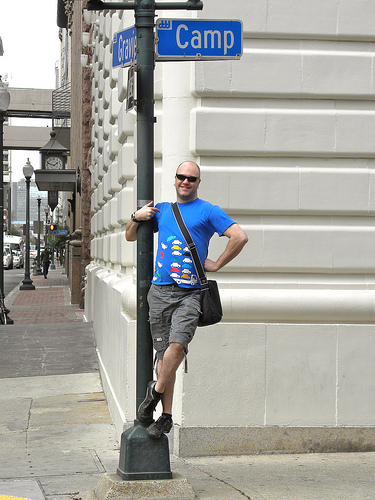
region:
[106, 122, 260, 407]
man hugging the pole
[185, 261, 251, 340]
the bag is black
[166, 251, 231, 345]
the bag is black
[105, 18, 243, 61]
A blue and white street sign.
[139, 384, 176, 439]
A black pair of shoes.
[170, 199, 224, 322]
A black messenger bag.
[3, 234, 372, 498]
The sidewalk.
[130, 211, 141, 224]
A black wristwatch.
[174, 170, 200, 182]
A black pair of sunglasses.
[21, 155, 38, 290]
A street light.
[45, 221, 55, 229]
A crosswalk signal.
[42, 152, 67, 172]
A clock.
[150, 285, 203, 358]
A pair of grey cargo shorts.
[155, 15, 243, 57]
blue rectangle sign for Camp Street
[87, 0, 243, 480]
tall metal pole with signs on top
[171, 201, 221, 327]
man holding black messenger bag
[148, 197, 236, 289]
man wearing casual blue t-shirt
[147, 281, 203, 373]
man wearing dark grey cargo shorts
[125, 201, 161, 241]
right arm wrapped around pole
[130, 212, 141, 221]
watch on wrist of right arm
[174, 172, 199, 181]
man wearing dark sunglasses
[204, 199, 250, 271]
man with left arm on left waist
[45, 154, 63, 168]
clock on exterior of multi-story building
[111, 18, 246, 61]
blue street signs on a metal pole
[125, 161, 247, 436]
a man standing on a metal pole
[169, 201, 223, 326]
black leather bag around man's shoulder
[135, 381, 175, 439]
man wearing black shoes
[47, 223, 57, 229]
an orange pedestrian light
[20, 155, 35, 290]
a street lamp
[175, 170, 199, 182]
man wearing black sunglasses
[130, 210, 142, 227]
man wearing a watch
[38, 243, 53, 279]
a person walking on a sidewalk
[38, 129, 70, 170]
a clock hanging from a wall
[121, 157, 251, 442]
Man standing on the streetlamp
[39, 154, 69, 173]
Clock face above the sidewalk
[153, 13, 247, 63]
Blue street sign that says Camp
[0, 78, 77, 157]
Two walkways over the street that connect buildings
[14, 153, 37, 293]
Street lamp next to the clock face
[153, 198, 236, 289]
Blue T-shirt the man in wearing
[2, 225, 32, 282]
Traffic on the roadway to the left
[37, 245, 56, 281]
Person in black walking down the sidewalk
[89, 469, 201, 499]
Concrete podium that the street light sits on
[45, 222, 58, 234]
Red do not walk light